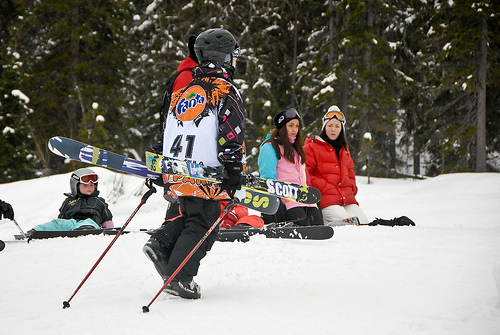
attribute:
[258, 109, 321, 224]
person — Sitting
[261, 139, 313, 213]
jacket — teal, pink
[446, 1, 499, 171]
tree — Tall , Green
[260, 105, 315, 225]
woman — blue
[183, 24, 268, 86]
helmet — black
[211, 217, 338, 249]
ski — black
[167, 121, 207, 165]
number — 41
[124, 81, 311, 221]
jacket — black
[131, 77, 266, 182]
jacket — white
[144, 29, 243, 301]
person — Standing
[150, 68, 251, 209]
jacket — black, white, and orange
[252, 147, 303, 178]
jacket — pink